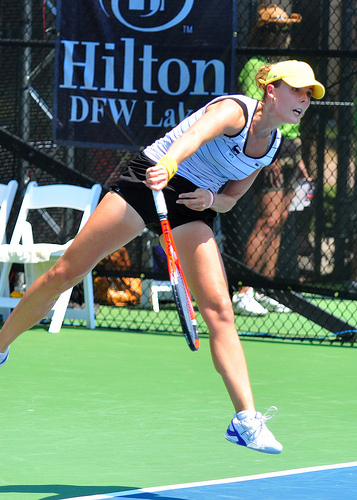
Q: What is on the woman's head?
A: A visor.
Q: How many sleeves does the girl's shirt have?
A: 0.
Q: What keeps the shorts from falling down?
A: Elastic waistband.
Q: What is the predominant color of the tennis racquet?
A: Orange.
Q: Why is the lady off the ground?
A: She jumped.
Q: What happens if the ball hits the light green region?
A: It's out.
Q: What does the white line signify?
A: Boundary.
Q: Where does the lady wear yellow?
A: Her head.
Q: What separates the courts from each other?
A: A fence.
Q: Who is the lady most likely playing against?
A: Another player.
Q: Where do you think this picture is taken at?
A: A tennis court.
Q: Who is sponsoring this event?
A: Hilton.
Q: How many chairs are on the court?
A: Two.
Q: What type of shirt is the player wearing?
A: Tank top.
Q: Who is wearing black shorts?
A: The woman player.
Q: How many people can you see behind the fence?
A: One.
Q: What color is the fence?
A: Black.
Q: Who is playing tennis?
A: A woman.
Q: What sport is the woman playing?
A: Tennis.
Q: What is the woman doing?
A: Playing tennis.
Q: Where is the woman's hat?
A: On her head.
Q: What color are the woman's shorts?
A: Black.